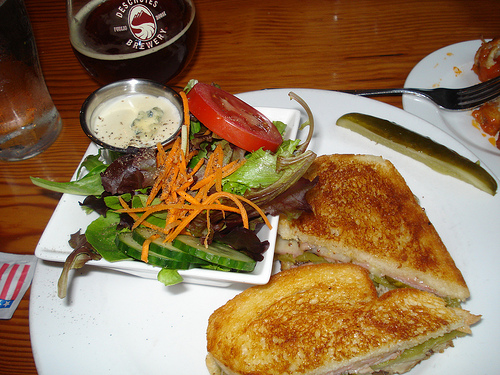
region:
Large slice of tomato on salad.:
[194, 84, 261, 186]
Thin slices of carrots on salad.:
[153, 156, 221, 256]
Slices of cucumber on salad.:
[124, 213, 240, 297]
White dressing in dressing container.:
[116, 96, 171, 163]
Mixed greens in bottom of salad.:
[78, 155, 187, 253]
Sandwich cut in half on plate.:
[303, 182, 418, 371]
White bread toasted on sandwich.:
[348, 332, 373, 357]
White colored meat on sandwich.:
[333, 321, 418, 371]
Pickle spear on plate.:
[346, 107, 469, 212]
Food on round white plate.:
[26, 122, 487, 357]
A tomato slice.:
[183, 70, 288, 164]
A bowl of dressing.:
[71, 70, 196, 156]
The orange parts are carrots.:
[148, 144, 233, 224]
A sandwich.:
[271, 145, 477, 318]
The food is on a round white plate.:
[30, 85, 499, 373]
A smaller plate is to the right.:
[382, 28, 499, 177]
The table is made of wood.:
[219, 2, 379, 81]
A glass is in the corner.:
[0, 2, 65, 157]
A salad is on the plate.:
[56, 74, 311, 282]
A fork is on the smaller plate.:
[315, 56, 499, 113]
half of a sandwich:
[205, 269, 460, 373]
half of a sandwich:
[279, 149, 479, 305]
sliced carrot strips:
[131, 141, 253, 235]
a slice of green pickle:
[327, 96, 498, 198]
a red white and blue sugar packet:
[3, 248, 38, 315]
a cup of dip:
[73, 73, 185, 165]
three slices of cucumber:
[108, 226, 251, 279]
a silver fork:
[327, 75, 498, 113]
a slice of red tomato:
[177, 76, 282, 156]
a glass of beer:
[65, 1, 210, 96]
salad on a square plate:
[54, 77, 276, 274]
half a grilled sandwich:
[209, 267, 474, 366]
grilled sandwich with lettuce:
[255, 142, 476, 369]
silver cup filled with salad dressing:
[84, 79, 181, 146]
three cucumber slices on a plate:
[114, 214, 254, 278]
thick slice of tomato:
[190, 74, 288, 151]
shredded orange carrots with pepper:
[146, 150, 244, 239]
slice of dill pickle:
[334, 105, 498, 198]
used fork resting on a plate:
[351, 67, 499, 116]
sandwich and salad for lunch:
[81, 84, 466, 366]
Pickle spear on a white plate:
[331, 110, 495, 198]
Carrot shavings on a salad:
[159, 150, 239, 233]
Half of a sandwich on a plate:
[277, 157, 472, 298]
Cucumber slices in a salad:
[116, 230, 255, 269]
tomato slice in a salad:
[183, 78, 283, 148]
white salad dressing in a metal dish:
[78, 80, 181, 157]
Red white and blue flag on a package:
[0, 247, 35, 321]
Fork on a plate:
[331, 75, 498, 109]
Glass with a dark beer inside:
[62, 2, 201, 84]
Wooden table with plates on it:
[224, 15, 398, 77]